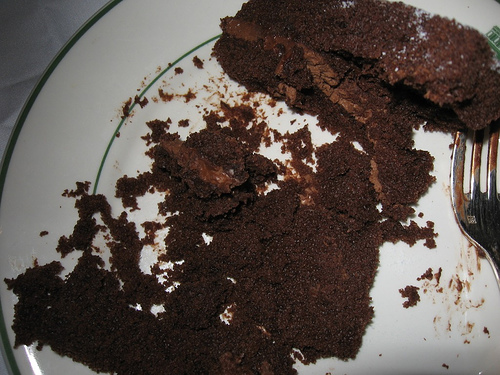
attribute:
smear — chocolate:
[431, 240, 490, 345]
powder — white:
[407, 9, 430, 48]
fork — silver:
[444, 120, 498, 290]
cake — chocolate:
[123, 146, 421, 343]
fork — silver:
[452, 127, 498, 284]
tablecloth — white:
[4, 15, 54, 68]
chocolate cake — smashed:
[21, 4, 496, 372]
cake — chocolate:
[134, 76, 418, 364]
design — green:
[473, 19, 500, 57]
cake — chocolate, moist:
[3, 1, 498, 373]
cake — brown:
[139, 70, 346, 352]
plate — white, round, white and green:
[0, 0, 499, 375]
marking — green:
[94, 102, 144, 168]